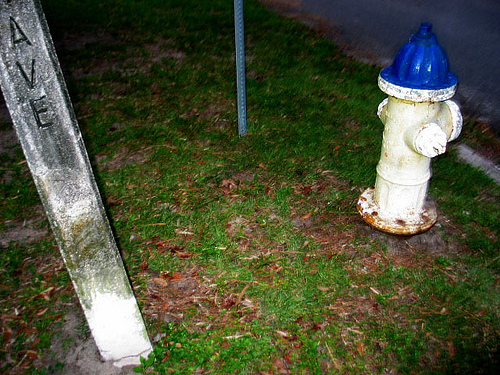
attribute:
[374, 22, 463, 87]
top — blue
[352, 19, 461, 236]
fire hydrant — blue, white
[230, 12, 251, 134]
pole — silver, metal, sign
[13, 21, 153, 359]
post — stone, street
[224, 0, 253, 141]
pole — metal, long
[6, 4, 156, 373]
pillar — concrete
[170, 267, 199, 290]
leaf — brownish red, red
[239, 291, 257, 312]
leaf — brownish red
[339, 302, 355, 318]
leaf — brownish red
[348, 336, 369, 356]
leaf — brownish red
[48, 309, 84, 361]
patch — dirt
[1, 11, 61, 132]
ave — pillar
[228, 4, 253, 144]
pole — green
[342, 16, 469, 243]
fire hydrant — rusty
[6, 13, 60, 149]
letters — gray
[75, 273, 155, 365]
smudges — white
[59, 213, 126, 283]
moss — green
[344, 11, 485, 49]
concrete — gray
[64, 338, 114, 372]
dirt — gray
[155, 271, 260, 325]
patches — brown